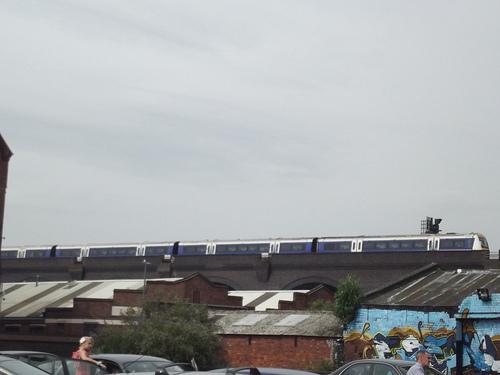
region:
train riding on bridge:
[2, 230, 492, 265]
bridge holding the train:
[1, 242, 499, 282]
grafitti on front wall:
[345, 293, 499, 374]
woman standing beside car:
[68, 331, 106, 373]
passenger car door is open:
[49, 353, 113, 374]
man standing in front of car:
[405, 343, 435, 374]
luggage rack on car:
[150, 363, 263, 373]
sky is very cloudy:
[4, 3, 499, 248]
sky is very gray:
[1, 0, 498, 247]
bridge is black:
[8, 244, 498, 292]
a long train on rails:
[0, 242, 490, 267]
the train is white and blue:
[0, 233, 490, 263]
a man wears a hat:
[72, 336, 107, 368]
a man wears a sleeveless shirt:
[71, 336, 108, 367]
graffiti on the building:
[341, 291, 499, 371]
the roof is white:
[0, 279, 311, 315]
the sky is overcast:
[0, 0, 499, 253]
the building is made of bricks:
[215, 333, 342, 368]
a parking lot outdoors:
[0, 348, 496, 373]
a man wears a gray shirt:
[407, 363, 427, 373]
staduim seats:
[0, 254, 170, 290]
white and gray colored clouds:
[3, 8, 78, 66]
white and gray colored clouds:
[13, 81, 97, 127]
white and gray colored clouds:
[34, 140, 130, 202]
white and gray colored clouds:
[81, 190, 192, 232]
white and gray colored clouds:
[187, 151, 277, 221]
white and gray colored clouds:
[310, 141, 400, 222]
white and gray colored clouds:
[387, 85, 479, 172]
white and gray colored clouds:
[89, 46, 176, 123]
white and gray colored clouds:
[212, 37, 350, 140]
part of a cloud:
[315, 146, 360, 176]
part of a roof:
[418, 298, 427, 312]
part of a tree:
[177, 314, 199, 321]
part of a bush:
[149, 325, 174, 353]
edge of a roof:
[244, 301, 299, 336]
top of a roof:
[93, 283, 99, 289]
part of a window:
[365, 356, 381, 368]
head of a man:
[418, 352, 440, 358]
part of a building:
[196, 273, 204, 290]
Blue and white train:
[17, 233, 490, 264]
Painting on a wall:
[346, 305, 498, 360]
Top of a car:
[333, 355, 415, 373]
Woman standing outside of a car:
[70, 335, 107, 372]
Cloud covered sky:
[199, 125, 307, 167]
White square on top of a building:
[232, 310, 266, 327]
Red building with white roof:
[228, 309, 342, 369]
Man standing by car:
[403, 347, 437, 372]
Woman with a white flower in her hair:
[78, 334, 95, 358]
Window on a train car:
[374, 235, 390, 249]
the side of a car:
[327, 359, 440, 374]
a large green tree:
[90, 293, 227, 367]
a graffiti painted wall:
[340, 295, 498, 372]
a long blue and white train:
[1, 235, 490, 260]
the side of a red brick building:
[220, 333, 346, 374]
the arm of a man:
[79, 347, 99, 367]